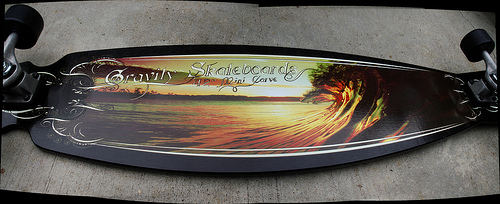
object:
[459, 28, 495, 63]
wheel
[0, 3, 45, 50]
wheel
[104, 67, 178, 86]
gravity word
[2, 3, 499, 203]
concrete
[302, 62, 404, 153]
cresting wave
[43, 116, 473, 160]
lower white border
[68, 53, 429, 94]
upper white boarder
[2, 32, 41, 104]
metal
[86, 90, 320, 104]
shore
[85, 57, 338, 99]
sky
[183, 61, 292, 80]
skateboard word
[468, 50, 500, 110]
holder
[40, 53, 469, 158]
design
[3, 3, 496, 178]
skateboard